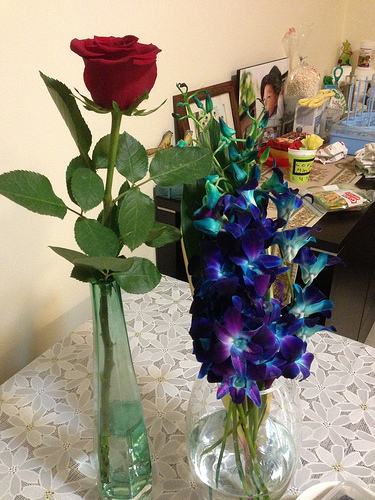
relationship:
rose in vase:
[61, 21, 170, 128] [78, 265, 155, 495]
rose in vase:
[69, 33, 162, 284] [78, 265, 155, 495]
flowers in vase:
[174, 81, 338, 398] [178, 382, 303, 499]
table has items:
[275, 188, 374, 312] [240, 66, 372, 204]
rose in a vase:
[69, 33, 162, 284] [78, 265, 155, 495]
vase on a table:
[78, 265, 155, 495] [0, 274, 372, 499]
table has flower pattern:
[0, 274, 372, 499] [6, 366, 89, 486]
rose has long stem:
[61, 21, 170, 128] [86, 112, 122, 272]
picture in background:
[232, 57, 299, 133] [163, 5, 374, 75]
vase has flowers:
[178, 382, 303, 499] [174, 81, 338, 398]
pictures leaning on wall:
[232, 57, 299, 133] [6, 5, 374, 37]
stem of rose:
[86, 112, 122, 272] [61, 21, 170, 128]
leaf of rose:
[37, 68, 98, 153] [61, 21, 170, 128]